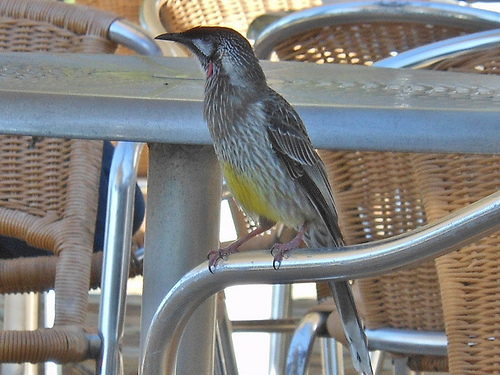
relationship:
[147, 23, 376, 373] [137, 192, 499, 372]
bird perched on chair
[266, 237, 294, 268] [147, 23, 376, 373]
foot from bird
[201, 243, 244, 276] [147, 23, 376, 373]
foot from bird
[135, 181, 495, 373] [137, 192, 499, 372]
metal arm of chair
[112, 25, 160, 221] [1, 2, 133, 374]
metal arm of chair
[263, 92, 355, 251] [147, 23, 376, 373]
side wing of bird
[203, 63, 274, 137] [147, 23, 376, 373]
neck feathers of bird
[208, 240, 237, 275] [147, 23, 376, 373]
claw of bird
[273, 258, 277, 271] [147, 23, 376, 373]
claws of bird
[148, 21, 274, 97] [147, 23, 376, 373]
head of bird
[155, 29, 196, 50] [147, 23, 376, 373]
beak of bird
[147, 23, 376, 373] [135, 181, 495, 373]
bird on metal arm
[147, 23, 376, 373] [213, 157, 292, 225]
bird has belly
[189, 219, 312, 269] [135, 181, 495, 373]
claws are on metal arm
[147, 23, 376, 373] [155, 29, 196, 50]
bird has beak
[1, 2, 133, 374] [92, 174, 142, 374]
chair has leg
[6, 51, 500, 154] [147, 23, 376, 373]
table next to bird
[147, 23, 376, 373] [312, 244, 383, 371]
bird has tailfeathers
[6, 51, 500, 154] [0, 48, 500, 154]
table held by table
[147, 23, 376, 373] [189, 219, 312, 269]
bird has claws